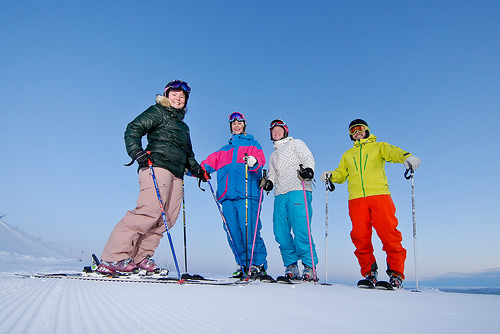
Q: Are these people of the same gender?
A: Yes, all the people are female.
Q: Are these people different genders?
A: No, all the people are female.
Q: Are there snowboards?
A: No, there are no snowboards.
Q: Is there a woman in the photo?
A: Yes, there is a woman.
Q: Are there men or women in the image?
A: Yes, there is a woman.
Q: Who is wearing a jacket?
A: The woman is wearing a jacket.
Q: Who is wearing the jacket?
A: The woman is wearing a jacket.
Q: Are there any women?
A: Yes, there is a woman.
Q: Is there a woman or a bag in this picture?
A: Yes, there is a woman.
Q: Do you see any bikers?
A: No, there are no bikers.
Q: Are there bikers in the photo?
A: No, there are no bikers.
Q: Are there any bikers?
A: No, there are no bikers.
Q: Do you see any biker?
A: No, there are no bikers.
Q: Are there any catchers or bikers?
A: No, there are no bikers or catchers.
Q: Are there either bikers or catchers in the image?
A: No, there are no bikers or catchers.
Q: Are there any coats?
A: Yes, there is a coat.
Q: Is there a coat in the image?
A: Yes, there is a coat.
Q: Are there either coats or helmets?
A: Yes, there is a coat.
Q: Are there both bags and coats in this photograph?
A: No, there is a coat but no bags.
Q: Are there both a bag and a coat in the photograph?
A: No, there is a coat but no bags.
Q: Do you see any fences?
A: No, there are no fences.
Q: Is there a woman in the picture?
A: Yes, there is a woman.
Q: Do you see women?
A: Yes, there is a woman.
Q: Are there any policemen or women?
A: Yes, there is a woman.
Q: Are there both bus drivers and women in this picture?
A: No, there is a woman but no bus drivers.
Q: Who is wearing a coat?
A: The woman is wearing a coat.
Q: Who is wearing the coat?
A: The woman is wearing a coat.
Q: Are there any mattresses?
A: No, there are no mattresses.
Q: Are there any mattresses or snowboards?
A: No, there are no mattresses or snowboards.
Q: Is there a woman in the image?
A: Yes, there is a woman.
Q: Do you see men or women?
A: Yes, there is a woman.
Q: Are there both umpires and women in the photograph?
A: No, there is a woman but no umpires.